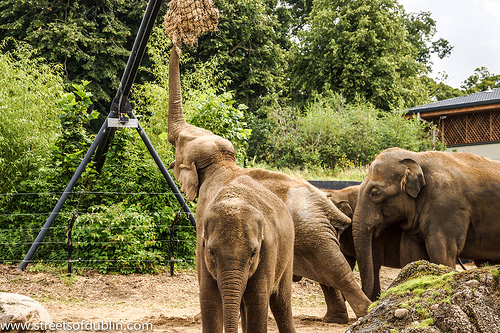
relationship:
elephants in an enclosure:
[161, 39, 491, 333] [3, 6, 496, 328]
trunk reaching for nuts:
[158, 41, 193, 124] [159, 2, 225, 53]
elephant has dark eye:
[189, 170, 304, 332] [247, 246, 258, 263]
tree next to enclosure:
[1, 9, 160, 191] [3, 6, 496, 328]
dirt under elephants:
[5, 277, 366, 333] [161, 39, 491, 333]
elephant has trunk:
[158, 45, 273, 176] [158, 41, 193, 124]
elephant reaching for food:
[158, 45, 273, 176] [159, 2, 225, 53]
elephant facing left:
[343, 139, 500, 295] [2, 4, 29, 328]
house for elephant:
[397, 88, 500, 153] [189, 170, 304, 332]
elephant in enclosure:
[189, 170, 304, 332] [3, 6, 496, 328]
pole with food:
[11, 1, 191, 273] [159, 2, 225, 53]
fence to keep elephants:
[0, 181, 196, 271] [161, 39, 491, 333]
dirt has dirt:
[0, 276, 392, 333] [5, 277, 366, 333]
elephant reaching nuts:
[158, 45, 273, 176] [159, 2, 225, 53]